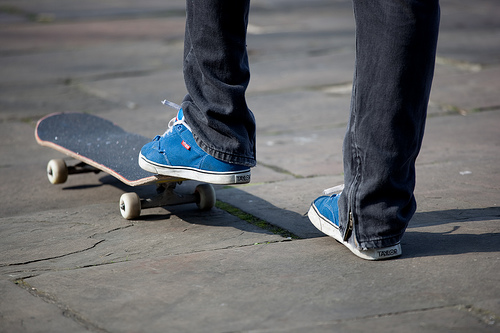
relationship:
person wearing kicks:
[138, 0, 434, 260] [137, 107, 407, 272]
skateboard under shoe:
[24, 103, 219, 231] [128, 98, 255, 195]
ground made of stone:
[1, 1, 499, 331] [6, 218, 496, 332]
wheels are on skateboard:
[45, 156, 226, 240] [24, 103, 219, 231]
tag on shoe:
[175, 138, 197, 157] [128, 98, 255, 195]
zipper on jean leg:
[344, 208, 367, 240] [330, 0, 438, 253]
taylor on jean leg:
[370, 242, 403, 258] [330, 0, 438, 253]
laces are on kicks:
[157, 92, 360, 207] [137, 107, 407, 272]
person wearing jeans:
[138, 0, 434, 260] [182, 0, 437, 260]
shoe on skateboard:
[128, 98, 255, 195] [24, 103, 219, 231]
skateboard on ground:
[24, 103, 219, 231] [1, 1, 499, 331]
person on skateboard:
[138, 0, 434, 260] [24, 103, 219, 231]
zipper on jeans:
[344, 208, 367, 240] [182, 0, 437, 260]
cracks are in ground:
[20, 186, 294, 280] [1, 1, 499, 331]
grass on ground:
[211, 190, 300, 247] [1, 1, 499, 331]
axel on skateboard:
[138, 186, 199, 218] [24, 103, 219, 231]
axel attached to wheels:
[138, 186, 199, 218] [45, 156, 226, 240]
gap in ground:
[212, 199, 306, 247] [1, 1, 499, 331]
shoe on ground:
[297, 179, 420, 268] [1, 1, 499, 331]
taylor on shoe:
[370, 242, 403, 258] [297, 179, 420, 268]